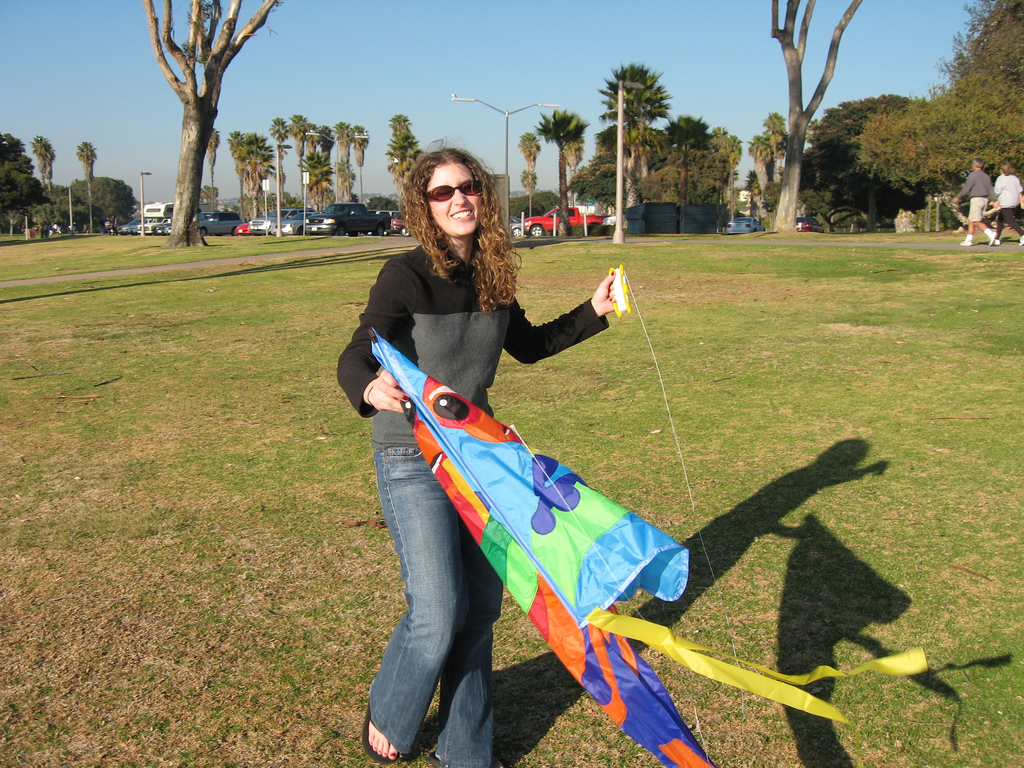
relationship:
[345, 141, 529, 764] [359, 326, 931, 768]
woman holding kite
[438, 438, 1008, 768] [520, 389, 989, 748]
shadow marking ground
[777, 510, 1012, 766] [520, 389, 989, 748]
shadow marking ground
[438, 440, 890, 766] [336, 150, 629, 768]
shadow to left of woman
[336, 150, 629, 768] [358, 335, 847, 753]
woman holding kite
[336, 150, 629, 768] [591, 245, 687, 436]
woman holding twine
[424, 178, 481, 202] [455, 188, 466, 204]
glasses setting on nose